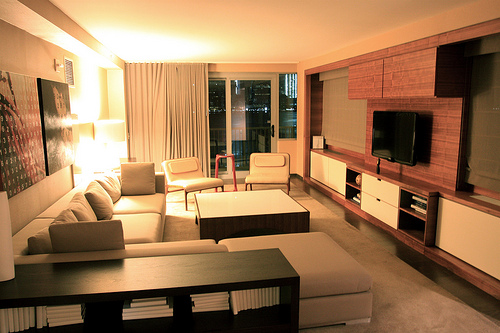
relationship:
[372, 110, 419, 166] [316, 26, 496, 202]
television mounted wall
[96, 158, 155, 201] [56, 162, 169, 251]
pillows are on couch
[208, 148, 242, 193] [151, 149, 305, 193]
table between chairs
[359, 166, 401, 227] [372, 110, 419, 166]
drawers are under television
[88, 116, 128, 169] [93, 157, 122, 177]
lamp sitting on table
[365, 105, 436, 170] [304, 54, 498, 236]
television mounted wall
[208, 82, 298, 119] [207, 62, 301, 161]
lights are visible in window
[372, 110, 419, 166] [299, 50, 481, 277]
television attached to wall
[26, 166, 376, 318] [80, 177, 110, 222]
chair with pillow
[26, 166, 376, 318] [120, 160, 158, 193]
chair with pillow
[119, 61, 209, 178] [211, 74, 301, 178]
curtains in front of window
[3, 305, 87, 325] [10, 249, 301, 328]
books on cabinet